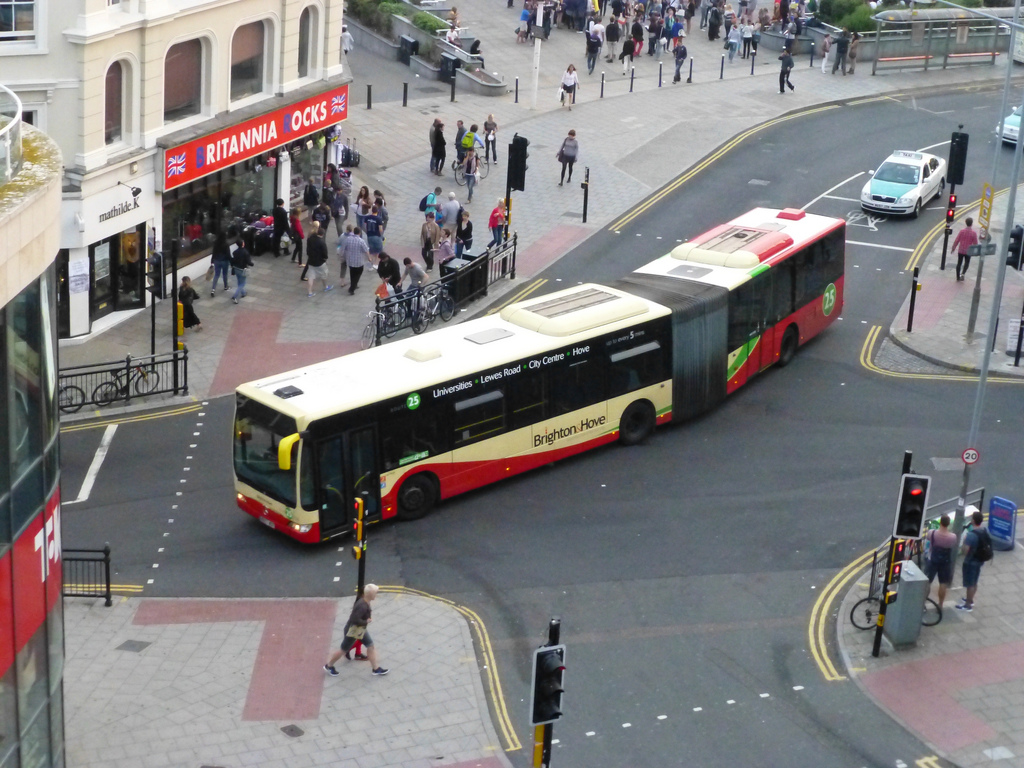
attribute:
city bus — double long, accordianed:
[224, 162, 866, 552]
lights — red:
[872, 463, 931, 570]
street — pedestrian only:
[546, 0, 791, 89]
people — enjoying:
[254, 178, 505, 328]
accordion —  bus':
[610, 269, 736, 421]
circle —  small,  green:
[405, 392, 423, 414]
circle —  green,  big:
[405, 385, 431, 407]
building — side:
[15, 177, 109, 763]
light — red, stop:
[865, 438, 937, 607]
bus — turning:
[204, 155, 868, 579]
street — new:
[126, 224, 984, 752]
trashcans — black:
[432, 245, 489, 306]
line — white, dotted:
[108, 390, 206, 565]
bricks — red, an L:
[127, 584, 354, 729]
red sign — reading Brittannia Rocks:
[136, 72, 383, 183]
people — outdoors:
[197, 154, 547, 314]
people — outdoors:
[292, 571, 413, 695]